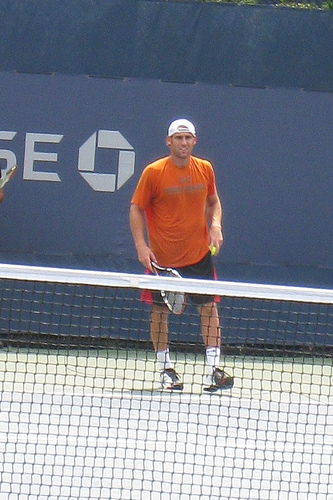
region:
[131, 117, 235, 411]
a tennis player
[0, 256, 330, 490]
a tennis court net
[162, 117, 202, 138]
man wearing a white cap backwards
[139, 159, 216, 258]
man wearing an orange T-shirt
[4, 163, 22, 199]
tip of a tennis racket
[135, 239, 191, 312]
man holding a tennis racket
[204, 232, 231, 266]
man holding a yellow ball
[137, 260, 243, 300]
man wearing black and red shorts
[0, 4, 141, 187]
blue tarp with a white logo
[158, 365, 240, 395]
man wearing black and white sneakers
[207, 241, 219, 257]
tennis ball in players hand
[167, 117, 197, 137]
baseball cap being worn backwards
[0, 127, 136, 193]
advertising at tennis match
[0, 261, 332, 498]
dividing net on tennis court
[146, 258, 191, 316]
tennis racket in players hand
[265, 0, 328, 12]
leaves of a tree in the background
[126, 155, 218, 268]
orange shirt worn by tennis player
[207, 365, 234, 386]
tennis shoes worn by tennis player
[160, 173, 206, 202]
logo on a T-shirt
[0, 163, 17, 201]
tennis racket being held by someone out of frame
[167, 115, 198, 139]
White ball cap turned around backwards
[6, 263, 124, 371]
Black and white tennis net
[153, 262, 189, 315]
Tennis racket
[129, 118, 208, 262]
Man wearing an orange shirt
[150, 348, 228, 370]
White crew socks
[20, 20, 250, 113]
Blue tarp backdrop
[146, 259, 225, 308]
Red and black shorts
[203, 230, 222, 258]
Hand with a tennis ball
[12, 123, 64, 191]
White letter E on blue backdrop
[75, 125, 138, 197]
White Chase Bank symbol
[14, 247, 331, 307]
top of tennis net is white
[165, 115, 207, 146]
the man's wearing ball cap backwards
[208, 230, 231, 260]
man holding a tennis ball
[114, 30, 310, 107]
the wall is blue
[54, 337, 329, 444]
the tennis netting is black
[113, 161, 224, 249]
man's shirt is orange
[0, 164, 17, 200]
a person in the background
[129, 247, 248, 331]
man's shorts are black and red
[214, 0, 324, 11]
trees on the other side of wall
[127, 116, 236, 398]
a tennis player is on the court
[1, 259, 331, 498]
a net is over the court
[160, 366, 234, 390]
the man is wearing tennis shoes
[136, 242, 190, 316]
the man is holding the racket in his right hand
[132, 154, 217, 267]
the boy is wearing an orange t-shirt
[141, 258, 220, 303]
the shorts are black with a red stripe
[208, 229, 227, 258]
the man is holding the tennis ball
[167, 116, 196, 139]
the player has his cap on backwards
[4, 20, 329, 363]
a blue wall is behind the player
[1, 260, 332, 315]
a white strip is on top of the net